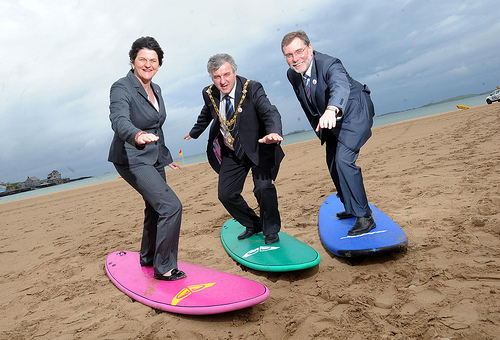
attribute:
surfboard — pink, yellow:
[104, 248, 268, 315]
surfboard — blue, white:
[317, 190, 407, 260]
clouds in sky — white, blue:
[1, 4, 500, 208]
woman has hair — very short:
[128, 38, 164, 75]